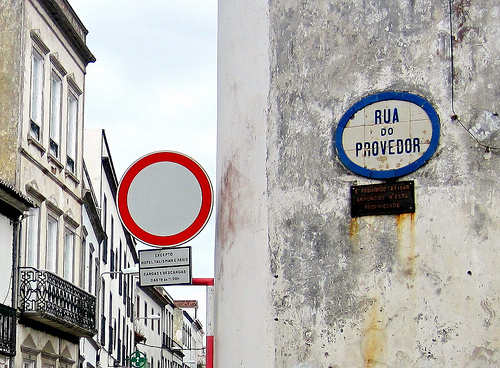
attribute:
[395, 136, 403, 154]
letter — written in blue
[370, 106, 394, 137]
letter — written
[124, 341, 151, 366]
sign — white, green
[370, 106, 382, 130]
letter — blue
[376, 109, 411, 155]
letter — written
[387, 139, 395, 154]
letter — blue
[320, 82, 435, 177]
plaque — white, blue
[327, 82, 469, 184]
words — blue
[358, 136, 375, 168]
letter — blue 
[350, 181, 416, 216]
sign — black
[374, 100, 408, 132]
letter — written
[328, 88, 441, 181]
sign — blue, circular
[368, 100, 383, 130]
letter — written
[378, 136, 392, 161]
letter — blue 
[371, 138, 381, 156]
letter — blue 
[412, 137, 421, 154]
letter — written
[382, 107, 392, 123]
letter — written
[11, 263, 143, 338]
patio — wire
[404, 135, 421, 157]
letter — blue 